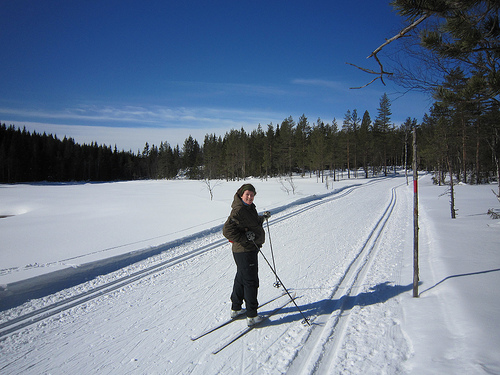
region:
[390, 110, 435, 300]
a tall wooden pole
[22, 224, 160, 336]
tracks in the snow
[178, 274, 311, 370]
skis on the ground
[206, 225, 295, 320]
black snow pants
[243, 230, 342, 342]
ski poles on the skier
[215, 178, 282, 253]
a brown jacket on the skier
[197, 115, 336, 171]
trees lining the woods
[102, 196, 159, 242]
fresh snow on the ground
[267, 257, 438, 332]
a womans shadow in the snow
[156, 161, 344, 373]
a woman skiing in the snow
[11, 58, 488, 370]
a winter day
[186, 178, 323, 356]
a woman is skiing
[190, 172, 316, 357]
a woman on skis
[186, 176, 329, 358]
the woman is cross country skiing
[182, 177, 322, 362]
the woman skis on a road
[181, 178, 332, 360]
the woman is smiling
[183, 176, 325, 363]
the woman is holding ski poles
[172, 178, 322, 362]
the woman is wearing a heavy coat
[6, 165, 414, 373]
the road is next to a field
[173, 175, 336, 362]
the surface that she skis on is level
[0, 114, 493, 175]
Forested area in the background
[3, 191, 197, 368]
Ice, ice everywhere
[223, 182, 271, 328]
A skier striking a pose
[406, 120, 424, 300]
Dead stump of a tree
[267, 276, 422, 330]
Shadow of the skier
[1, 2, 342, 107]
Blue sky background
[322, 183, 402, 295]
Fresh tracks in the ice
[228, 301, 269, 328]
Ski boots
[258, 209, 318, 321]
Ski poles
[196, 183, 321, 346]
Woman fully dressded in ski gear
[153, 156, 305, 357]
person skiing on snow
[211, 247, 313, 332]
ski poles on the snow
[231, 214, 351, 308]
ski poles in person's hand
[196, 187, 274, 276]
woman wearing green ski jacket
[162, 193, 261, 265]
large green ski jacket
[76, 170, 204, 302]
tire marks in the snow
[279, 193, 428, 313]
more tire marks in the snow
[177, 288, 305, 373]
skis on womans feet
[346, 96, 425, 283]
piece of a tree in the snow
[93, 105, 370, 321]
trees in the snow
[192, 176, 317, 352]
A woman skiing in heavy snow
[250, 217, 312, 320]
The woman is holding skipoles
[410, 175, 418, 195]
A piece of red tape on the stick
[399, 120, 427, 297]
A large wooden stick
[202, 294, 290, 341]
Snow covered skis beneath the woman's feet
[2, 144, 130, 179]
Green trees in the background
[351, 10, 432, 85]
A branch hanging over the woman's head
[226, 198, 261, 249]
A brown jacket on the woman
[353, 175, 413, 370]
Tracks are visible in the snow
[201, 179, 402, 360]
A path through the snow has been made